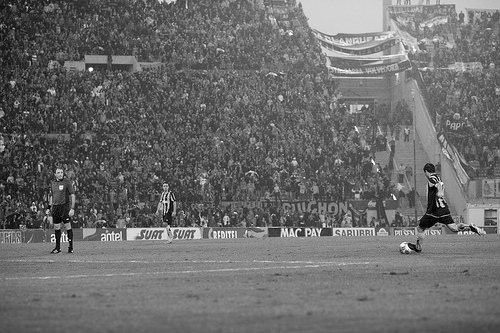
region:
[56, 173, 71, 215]
a soccer referee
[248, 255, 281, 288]
section of a soccer pitch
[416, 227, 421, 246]
left leg of a soccer player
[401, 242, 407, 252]
part of a football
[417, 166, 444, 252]
soccer player going to hit the ball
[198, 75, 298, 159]
section of the spectators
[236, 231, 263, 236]
section of the advertising board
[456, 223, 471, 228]
right foot of a soccer player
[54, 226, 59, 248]
right foot of a referee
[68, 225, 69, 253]
left leg of a referee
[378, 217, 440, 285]
Man is about to kick soccer ball.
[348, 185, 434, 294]
Soccer ball near man's foot.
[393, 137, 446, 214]
Man has dark hair.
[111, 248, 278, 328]
White lines on soccer field.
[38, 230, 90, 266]
Man wearing dark socks.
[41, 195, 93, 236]
Man wearing dark shorts.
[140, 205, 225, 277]
Man wearing dark shorts.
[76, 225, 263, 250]
Writing on wall around soccer field.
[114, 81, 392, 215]
Many people in the stands at the soccer game.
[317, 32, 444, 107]
Banners strung across stadium sides.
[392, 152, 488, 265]
a kid kicking a soccer ball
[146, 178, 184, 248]
a person in a striped shirt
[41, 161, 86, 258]
a man in black socks standing on the field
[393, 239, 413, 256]
a soccer ball about to be kicked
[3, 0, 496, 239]
a stadium full of spectators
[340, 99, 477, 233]
a large stairwell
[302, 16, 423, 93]
banners hanging over the stairwell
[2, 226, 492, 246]
sponsor banners along the edge of the field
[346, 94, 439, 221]
people walking up and down the stairs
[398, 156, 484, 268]
a person wearing black about to kick the ball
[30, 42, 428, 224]
spectators watching soccor game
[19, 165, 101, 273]
man standing in soccer field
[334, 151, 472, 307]
man kicking soccer ball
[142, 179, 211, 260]
referee watching soccer game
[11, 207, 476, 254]
barricade with advertisements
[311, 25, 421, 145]
four banners hung in stadium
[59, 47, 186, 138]
entrance to the bleachers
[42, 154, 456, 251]
two players wear different color shirts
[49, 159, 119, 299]
wearing black knee high socks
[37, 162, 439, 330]
only 2 players on fiedl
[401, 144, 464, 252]
A player kicking a ball on the soccer field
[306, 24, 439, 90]
Banners over a staircase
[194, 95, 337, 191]
A stadium full of fans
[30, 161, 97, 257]
A player standing on the soccer field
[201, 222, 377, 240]
Advertisements line the border with the stadium seating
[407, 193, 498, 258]
A runner's back leg kicked back in the air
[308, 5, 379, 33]
A grey sky outside the stadium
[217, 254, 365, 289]
White lines on the soccer field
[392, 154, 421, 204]
People going up the stairs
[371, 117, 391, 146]
A metal hand rail on the stairs